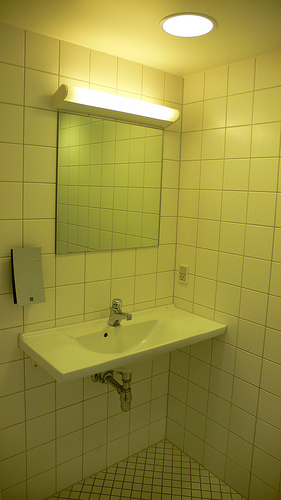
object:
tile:
[190, 246, 219, 279]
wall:
[167, 51, 279, 498]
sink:
[18, 303, 227, 385]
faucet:
[107, 295, 132, 327]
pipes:
[91, 366, 134, 412]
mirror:
[55, 112, 164, 255]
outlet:
[176, 263, 188, 284]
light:
[161, 13, 216, 38]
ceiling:
[0, 0, 280, 78]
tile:
[163, 458, 173, 467]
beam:
[64, 79, 178, 123]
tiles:
[38, 438, 253, 500]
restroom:
[0, 0, 280, 499]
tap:
[112, 299, 122, 306]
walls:
[1, 18, 178, 500]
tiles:
[0, 21, 280, 499]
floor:
[35, 438, 251, 500]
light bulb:
[182, 17, 195, 28]